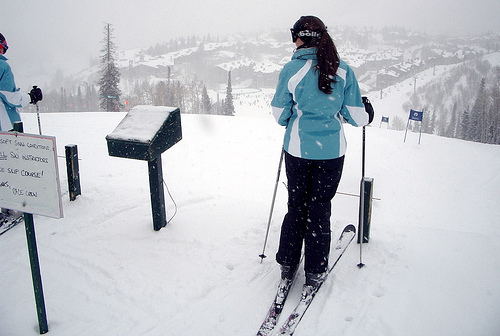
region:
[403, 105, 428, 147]
ski marker in snow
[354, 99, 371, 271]
ski pole in girl's hand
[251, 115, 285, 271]
ski pole in snow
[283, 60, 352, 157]
jacket on girl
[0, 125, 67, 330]
warning sign in snow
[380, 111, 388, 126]
ski marker in snow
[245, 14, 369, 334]
girl in skis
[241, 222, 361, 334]
girl in skis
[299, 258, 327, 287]
ski boot on girl foot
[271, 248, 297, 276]
ski boot on girl foot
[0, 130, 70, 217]
Sign warning about ski slope conditions.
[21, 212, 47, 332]
Black pole holding up ski slope warning sign.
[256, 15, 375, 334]
A girl in blue and black with black goggles.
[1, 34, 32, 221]
A person in blue and black with red ski goggles.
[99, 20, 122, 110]
Large tree on the left side of the slope.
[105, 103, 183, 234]
Black box on a post at the top of the slope.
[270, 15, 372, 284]
A girl with long dark hair getting ready to ski.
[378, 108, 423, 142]
Two blue ski coarse markers.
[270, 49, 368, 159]
Blue and white jacket on a woman with long hair.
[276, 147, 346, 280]
Black ski pants on a woman with long hair.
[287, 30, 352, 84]
woman has black cap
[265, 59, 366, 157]
blue and white jacket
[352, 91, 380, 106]
woman has black gloves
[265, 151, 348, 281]
woman has black pants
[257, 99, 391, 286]
woman holds grey ski poles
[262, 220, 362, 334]
woman has black skis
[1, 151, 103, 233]
white sign behind women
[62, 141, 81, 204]
black gates near women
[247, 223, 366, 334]
skis are snow covered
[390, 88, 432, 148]
blue gates down slope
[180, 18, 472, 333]
a woman on skies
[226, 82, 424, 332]
a woman standing on skies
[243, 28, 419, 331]
a woman skiing on the snow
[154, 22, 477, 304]
a woman skiing on white snow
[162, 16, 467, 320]
a mountain covered in snow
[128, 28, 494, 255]
a mountain covered in white snow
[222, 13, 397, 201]
a woman holding ski poles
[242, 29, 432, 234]
a woman holding a jacket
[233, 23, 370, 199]
a woman wearing a blue jacket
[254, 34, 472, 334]
a woman wearing pants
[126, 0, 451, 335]
woman standing on skie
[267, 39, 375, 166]
woman wearing blue jacket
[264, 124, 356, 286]
woman wearing black pants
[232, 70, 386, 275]
woman holding ski poles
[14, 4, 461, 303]
snow falling from sky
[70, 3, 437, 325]
woman standing next to box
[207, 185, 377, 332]
snow on top of skis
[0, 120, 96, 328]
white sign with black writing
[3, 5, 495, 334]
woman standing on top of hill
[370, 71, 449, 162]
blue marker in snow